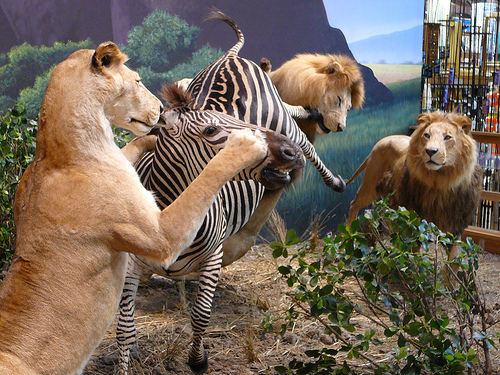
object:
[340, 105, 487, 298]
lion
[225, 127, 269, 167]
paw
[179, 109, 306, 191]
face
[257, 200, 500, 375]
bush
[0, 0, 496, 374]
wildlife exhibit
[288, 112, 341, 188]
zebra's leg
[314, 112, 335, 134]
lion's mouth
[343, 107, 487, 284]
lion watching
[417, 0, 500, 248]
bookcase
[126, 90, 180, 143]
lion biting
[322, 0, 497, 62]
sky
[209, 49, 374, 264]
lion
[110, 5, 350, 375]
zebra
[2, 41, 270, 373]
brown lion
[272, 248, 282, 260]
leaves